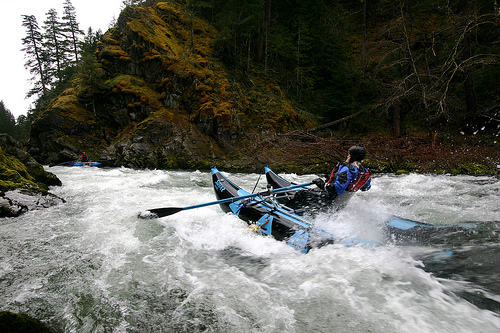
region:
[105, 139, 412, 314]
Someone is river rafting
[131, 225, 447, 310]
The water is white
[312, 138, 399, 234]
The person is wearing blue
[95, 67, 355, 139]
The vegetation is green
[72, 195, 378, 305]
The water is flowing fast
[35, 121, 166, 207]
There is another person in the distance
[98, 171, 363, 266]
The person has a paddle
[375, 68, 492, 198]
There are trees on the hill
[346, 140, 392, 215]
The person has a helmet on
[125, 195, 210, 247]
The end of the paddle is black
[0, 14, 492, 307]
A person white water rafting in a beautiful area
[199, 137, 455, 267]
a person white water rafting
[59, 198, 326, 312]
white water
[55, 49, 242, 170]
large rocks covered in moss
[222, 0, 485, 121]
trees growing on a rock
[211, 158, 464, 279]
blue raft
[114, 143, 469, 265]
white water rafting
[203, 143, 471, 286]
person on a blue raft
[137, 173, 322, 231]
long rafting paddle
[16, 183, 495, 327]
white water in a river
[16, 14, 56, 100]
a green tree in a distance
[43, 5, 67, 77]
a green tree in a distance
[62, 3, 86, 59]
a green tree in a distance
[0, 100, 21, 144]
a green tree in a distance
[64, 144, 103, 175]
a person in a distance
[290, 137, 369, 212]
a person in a distance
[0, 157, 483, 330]
some clean water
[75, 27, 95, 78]
a green tree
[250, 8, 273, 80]
a green tree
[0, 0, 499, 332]
it is a daytime scene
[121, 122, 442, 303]
BLACK AND NEON BLUE WATER RAFT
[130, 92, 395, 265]
BLACK AND NEON BLUE WATER RAFT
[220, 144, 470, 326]
BLACK AND NEON BLUE WATER RAFT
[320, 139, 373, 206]
a rafter in a blue jacket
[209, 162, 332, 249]
a light blue and black raft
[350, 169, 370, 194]
the rafter's red backpack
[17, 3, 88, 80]
pine trees on a hill overlooking the river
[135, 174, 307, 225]
the rafter's black and light blue oar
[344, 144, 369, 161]
the rafter's black helmet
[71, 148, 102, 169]
another rafter in a black and light blue raft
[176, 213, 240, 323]
the rapids on the river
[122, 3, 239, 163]
rocks overlooking the river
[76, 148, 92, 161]
a rafter in a black and red jacket